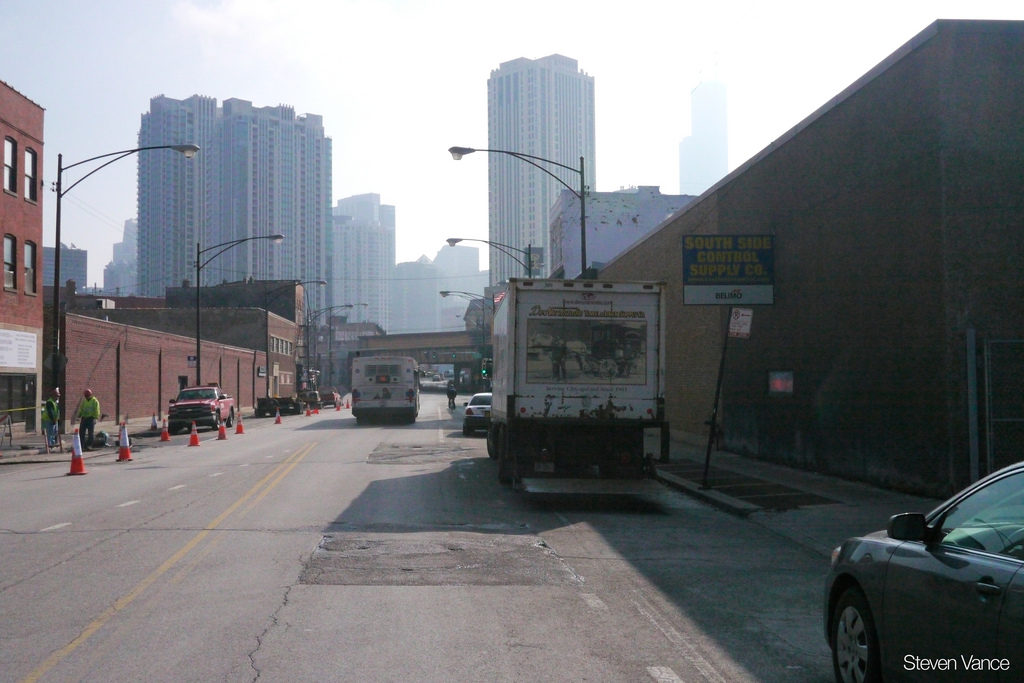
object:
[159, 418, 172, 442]
cone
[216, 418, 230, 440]
cone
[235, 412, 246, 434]
cone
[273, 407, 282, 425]
cone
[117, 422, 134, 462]
cone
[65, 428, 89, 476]
cone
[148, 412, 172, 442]
cone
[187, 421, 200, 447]
cone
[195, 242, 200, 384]
light pole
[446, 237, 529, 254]
building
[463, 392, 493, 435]
car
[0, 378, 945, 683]
paved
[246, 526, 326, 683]
street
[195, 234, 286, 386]
pole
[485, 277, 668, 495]
delivery truck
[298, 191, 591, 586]
signs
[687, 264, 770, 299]
sign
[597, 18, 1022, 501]
building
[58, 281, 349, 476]
row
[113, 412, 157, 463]
cones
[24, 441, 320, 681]
lines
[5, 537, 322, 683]
pavement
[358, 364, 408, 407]
bus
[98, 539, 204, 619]
line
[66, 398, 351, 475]
traffic cones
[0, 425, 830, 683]
street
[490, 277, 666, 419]
white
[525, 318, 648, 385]
truck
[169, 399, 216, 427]
pick-up truck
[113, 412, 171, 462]
cones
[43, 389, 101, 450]
two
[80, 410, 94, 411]
vests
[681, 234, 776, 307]
sign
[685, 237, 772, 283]
lettering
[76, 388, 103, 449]
man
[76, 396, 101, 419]
jacket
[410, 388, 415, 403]
brake light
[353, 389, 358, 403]
brake light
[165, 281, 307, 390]
building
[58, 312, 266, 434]
wall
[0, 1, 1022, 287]
sky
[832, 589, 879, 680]
tire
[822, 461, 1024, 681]
car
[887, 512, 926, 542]
mirror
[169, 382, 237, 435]
car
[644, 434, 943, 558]
sidewalk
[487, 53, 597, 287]
building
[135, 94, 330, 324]
building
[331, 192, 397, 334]
building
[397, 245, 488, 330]
building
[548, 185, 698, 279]
building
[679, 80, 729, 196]
building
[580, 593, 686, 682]
lines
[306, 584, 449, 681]
road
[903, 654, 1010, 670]
words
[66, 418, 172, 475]
orange cones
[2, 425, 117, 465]
sidewalk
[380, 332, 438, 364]
bridge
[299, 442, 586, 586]
street